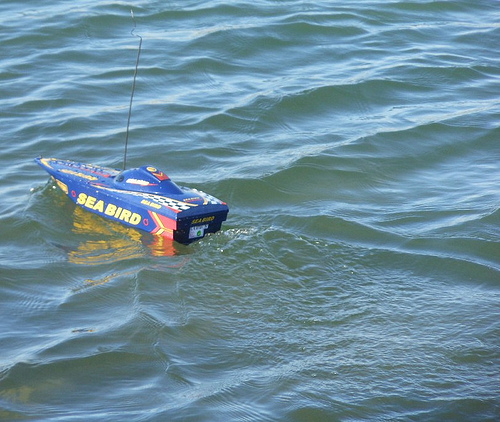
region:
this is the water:
[248, 238, 483, 418]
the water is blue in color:
[143, 349, 268, 398]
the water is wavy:
[255, 58, 461, 186]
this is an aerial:
[121, 2, 142, 179]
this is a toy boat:
[37, 126, 228, 237]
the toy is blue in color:
[88, 183, 134, 204]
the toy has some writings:
[70, 178, 140, 228]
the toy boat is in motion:
[36, 155, 231, 240]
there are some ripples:
[221, 255, 368, 316]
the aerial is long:
[117, 12, 144, 168]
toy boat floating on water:
[33, 66, 258, 261]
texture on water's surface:
[187, 217, 442, 387]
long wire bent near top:
[80, 0, 170, 206]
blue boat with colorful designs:
[26, 145, 227, 260]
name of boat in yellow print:
[25, 150, 240, 257]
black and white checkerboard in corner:
[125, 185, 195, 212]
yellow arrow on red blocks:
[145, 205, 181, 245]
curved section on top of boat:
[90, 156, 195, 197]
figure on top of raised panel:
[140, 157, 171, 187]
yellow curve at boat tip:
[20, 127, 80, 205]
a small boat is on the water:
[25, 27, 232, 278]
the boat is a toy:
[35, 5, 231, 251]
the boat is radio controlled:
[35, 6, 230, 246]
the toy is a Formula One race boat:
[32, 5, 228, 253]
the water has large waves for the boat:
[11, 5, 493, 395]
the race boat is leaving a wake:
[35, 151, 493, 416]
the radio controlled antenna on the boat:
[108, 3, 145, 238]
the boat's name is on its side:
[28, 148, 229, 246]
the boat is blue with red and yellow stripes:
[33, 151, 229, 251]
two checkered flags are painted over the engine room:
[144, 187, 226, 214]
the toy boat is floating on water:
[25, 136, 231, 248]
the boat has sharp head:
[30, 141, 85, 196]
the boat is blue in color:
[36, 149, 226, 236]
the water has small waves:
[13, 251, 463, 418]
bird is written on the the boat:
[108, 199, 143, 226]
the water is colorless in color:
[231, 2, 487, 415]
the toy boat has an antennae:
[113, 5, 146, 161]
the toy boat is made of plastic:
[20, 149, 210, 246]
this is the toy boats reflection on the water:
[70, 241, 137, 265]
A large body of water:
[173, 0, 498, 174]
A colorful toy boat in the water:
[25, 0, 237, 240]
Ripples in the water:
[203, 224, 496, 420]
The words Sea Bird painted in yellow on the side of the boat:
[76, 185, 143, 227]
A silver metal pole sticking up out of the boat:
[118, 5, 155, 174]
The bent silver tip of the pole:
[126, 5, 146, 40]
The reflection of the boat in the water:
[70, 219, 145, 283]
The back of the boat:
[176, 203, 236, 248]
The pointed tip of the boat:
[33, 135, 92, 199]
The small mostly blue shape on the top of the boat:
[108, 162, 180, 202]